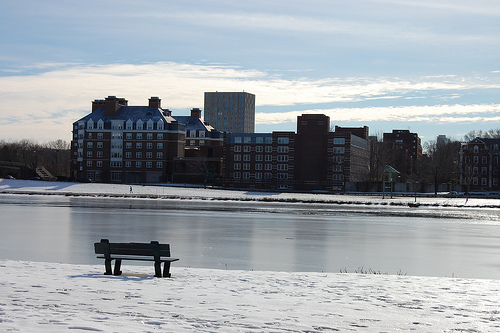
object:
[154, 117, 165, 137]
window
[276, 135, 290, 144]
window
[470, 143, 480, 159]
window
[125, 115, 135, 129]
window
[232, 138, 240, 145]
window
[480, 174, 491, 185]
window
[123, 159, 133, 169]
window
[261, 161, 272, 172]
window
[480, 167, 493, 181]
window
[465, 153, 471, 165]
window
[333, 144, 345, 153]
window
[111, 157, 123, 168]
window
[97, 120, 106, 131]
window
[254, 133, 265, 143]
window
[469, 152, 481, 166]
window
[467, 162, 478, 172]
window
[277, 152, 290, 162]
window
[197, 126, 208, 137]
window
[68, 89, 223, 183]
building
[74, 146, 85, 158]
window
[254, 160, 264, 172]
window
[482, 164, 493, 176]
window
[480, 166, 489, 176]
window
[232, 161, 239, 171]
window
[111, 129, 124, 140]
window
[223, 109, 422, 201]
building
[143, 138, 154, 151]
window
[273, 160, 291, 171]
window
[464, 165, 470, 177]
window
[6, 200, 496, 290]
river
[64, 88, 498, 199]
city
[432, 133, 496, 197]
building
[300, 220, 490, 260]
water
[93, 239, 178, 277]
bench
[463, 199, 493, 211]
body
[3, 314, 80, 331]
ground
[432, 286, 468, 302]
snow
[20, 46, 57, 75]
sky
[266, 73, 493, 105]
clouds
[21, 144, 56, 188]
trees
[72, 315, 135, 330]
snow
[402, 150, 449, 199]
trees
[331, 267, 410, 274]
grass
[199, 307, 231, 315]
snow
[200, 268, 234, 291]
beach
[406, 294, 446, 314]
floor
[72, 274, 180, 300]
footprints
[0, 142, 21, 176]
trees